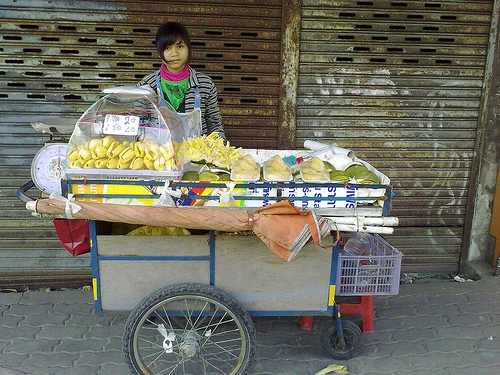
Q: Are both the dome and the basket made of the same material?
A: Yes, both the dome and the basket are made of plastic.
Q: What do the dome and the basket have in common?
A: The material, both the dome and the basket are plastic.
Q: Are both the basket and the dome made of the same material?
A: Yes, both the basket and the dome are made of plastic.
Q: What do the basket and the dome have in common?
A: The material, both the basket and the dome are plastic.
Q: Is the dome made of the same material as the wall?
A: No, the dome is made of plastic and the wall is made of metal.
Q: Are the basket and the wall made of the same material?
A: No, the basket is made of plastic and the wall is made of metal.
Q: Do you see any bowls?
A: No, there are no bowls.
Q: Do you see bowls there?
A: No, there are no bowls.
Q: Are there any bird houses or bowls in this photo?
A: No, there are no bowls or bird houses.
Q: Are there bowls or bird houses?
A: No, there are no bowls or bird houses.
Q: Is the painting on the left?
A: No, the painting is on the right of the image.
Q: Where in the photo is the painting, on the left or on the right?
A: The painting is on the right of the image.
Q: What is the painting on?
A: The painting is on the wall.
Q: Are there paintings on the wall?
A: Yes, there is a painting on the wall.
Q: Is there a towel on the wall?
A: No, there is a painting on the wall.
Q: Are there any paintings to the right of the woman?
A: Yes, there is a painting to the right of the woman.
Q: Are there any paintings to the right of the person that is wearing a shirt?
A: Yes, there is a painting to the right of the woman.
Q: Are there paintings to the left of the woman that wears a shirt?
A: No, the painting is to the right of the woman.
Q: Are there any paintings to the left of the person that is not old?
A: No, the painting is to the right of the woman.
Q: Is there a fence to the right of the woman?
A: No, there is a painting to the right of the woman.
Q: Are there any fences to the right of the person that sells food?
A: No, there is a painting to the right of the woman.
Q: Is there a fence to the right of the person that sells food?
A: No, there is a painting to the right of the woman.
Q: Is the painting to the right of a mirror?
A: No, the painting is to the right of the woman.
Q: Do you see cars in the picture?
A: No, there are no cars.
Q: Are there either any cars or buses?
A: No, there are no cars or buses.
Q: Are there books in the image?
A: No, there are no books.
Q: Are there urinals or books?
A: No, there are no books or urinals.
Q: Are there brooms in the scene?
A: No, there are no brooms.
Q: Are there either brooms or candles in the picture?
A: No, there are no brooms or candles.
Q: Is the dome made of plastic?
A: Yes, the dome is made of plastic.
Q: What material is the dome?
A: The dome is made of plastic.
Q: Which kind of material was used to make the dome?
A: The dome is made of plastic.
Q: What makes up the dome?
A: The dome is made of plastic.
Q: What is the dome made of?
A: The dome is made of plastic.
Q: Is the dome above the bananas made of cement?
A: No, the dome is made of plastic.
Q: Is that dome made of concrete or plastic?
A: The dome is made of plastic.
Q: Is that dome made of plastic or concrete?
A: The dome is made of plastic.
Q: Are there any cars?
A: No, there are no cars.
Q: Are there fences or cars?
A: No, there are no cars or fences.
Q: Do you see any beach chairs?
A: No, there are no beach chairs.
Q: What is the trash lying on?
A: The trash is lying on the sidewalk.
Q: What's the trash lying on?
A: The trash is lying on the sidewalk.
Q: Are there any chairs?
A: No, there are no chairs.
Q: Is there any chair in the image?
A: No, there are no chairs.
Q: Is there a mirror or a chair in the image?
A: No, there are no chairs or mirrors.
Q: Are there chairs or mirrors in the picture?
A: No, there are no chairs or mirrors.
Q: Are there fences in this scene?
A: No, there are no fences.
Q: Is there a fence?
A: No, there are no fences.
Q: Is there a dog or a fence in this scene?
A: No, there are no fences or dogs.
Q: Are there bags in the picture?
A: Yes, there is a bag.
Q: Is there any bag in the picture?
A: Yes, there is a bag.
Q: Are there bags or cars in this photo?
A: Yes, there is a bag.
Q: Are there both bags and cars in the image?
A: No, there is a bag but no cars.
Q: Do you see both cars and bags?
A: No, there is a bag but no cars.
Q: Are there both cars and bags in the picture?
A: No, there is a bag but no cars.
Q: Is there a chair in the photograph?
A: No, there are no chairs.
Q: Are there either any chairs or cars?
A: No, there are no chairs or cars.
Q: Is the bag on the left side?
A: Yes, the bag is on the left of the image.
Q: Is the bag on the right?
A: No, the bag is on the left of the image.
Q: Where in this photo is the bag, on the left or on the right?
A: The bag is on the left of the image.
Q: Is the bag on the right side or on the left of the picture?
A: The bag is on the left of the image.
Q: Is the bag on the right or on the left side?
A: The bag is on the left of the image.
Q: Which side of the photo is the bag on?
A: The bag is on the left of the image.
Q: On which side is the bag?
A: The bag is on the left of the image.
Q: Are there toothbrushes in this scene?
A: No, there are no toothbrushes.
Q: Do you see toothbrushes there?
A: No, there are no toothbrushes.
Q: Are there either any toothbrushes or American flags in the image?
A: No, there are no toothbrushes or American flags.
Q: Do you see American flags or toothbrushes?
A: No, there are no toothbrushes or American flags.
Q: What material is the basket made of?
A: The basket is made of plastic.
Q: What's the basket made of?
A: The basket is made of plastic.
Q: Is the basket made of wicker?
A: No, the basket is made of plastic.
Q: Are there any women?
A: Yes, there is a woman.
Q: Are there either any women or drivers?
A: Yes, there is a woman.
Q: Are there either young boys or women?
A: Yes, there is a young woman.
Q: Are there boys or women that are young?
A: Yes, the woman is young.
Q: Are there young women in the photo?
A: Yes, there is a young woman.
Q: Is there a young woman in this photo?
A: Yes, there is a young woman.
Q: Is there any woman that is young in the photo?
A: Yes, there is a young woman.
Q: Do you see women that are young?
A: Yes, there is a woman that is young.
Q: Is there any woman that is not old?
A: Yes, there is an young woman.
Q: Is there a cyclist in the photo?
A: No, there are no cyclists.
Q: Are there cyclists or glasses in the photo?
A: No, there are no cyclists or glasses.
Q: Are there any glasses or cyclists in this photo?
A: No, there are no cyclists or glasses.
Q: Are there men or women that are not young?
A: No, there is a woman but she is young.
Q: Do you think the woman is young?
A: Yes, the woman is young.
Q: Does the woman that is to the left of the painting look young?
A: Yes, the woman is young.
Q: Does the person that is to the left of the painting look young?
A: Yes, the woman is young.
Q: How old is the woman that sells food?
A: The woman is young.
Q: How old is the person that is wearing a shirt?
A: The woman is young.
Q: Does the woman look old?
A: No, the woman is young.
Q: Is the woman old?
A: No, the woman is young.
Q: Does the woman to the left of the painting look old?
A: No, the woman is young.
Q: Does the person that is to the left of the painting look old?
A: No, the woman is young.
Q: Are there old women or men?
A: No, there is a woman but she is young.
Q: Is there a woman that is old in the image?
A: No, there is a woman but she is young.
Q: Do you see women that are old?
A: No, there is a woman but she is young.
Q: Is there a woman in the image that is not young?
A: No, there is a woman but she is young.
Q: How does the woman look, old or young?
A: The woman is young.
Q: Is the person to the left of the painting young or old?
A: The woman is young.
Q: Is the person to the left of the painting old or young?
A: The woman is young.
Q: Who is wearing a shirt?
A: The woman is wearing a shirt.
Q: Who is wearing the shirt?
A: The woman is wearing a shirt.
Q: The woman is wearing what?
A: The woman is wearing a shirt.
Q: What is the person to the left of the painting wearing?
A: The woman is wearing a shirt.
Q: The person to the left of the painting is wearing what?
A: The woman is wearing a shirt.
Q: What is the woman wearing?
A: The woman is wearing a shirt.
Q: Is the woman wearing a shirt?
A: Yes, the woman is wearing a shirt.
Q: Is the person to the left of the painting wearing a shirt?
A: Yes, the woman is wearing a shirt.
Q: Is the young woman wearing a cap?
A: No, the woman is wearing a shirt.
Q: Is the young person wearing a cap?
A: No, the woman is wearing a shirt.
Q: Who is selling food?
A: The woman is selling food.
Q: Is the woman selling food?
A: Yes, the woman is selling food.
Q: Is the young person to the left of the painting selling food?
A: Yes, the woman is selling food.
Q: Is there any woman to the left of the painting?
A: Yes, there is a woman to the left of the painting.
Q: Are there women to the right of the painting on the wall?
A: No, the woman is to the left of the painting.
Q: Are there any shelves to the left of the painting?
A: No, there is a woman to the left of the painting.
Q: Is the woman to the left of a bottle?
A: No, the woman is to the left of the painting.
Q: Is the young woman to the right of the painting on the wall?
A: No, the woman is to the left of the painting.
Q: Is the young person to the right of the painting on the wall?
A: No, the woman is to the left of the painting.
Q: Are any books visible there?
A: No, there are no books.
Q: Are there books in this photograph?
A: No, there are no books.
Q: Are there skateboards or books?
A: No, there are no books or skateboards.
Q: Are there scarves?
A: Yes, there is a scarf.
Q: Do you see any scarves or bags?
A: Yes, there is a scarf.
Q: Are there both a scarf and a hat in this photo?
A: No, there is a scarf but no hats.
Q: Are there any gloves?
A: No, there are no gloves.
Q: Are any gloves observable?
A: No, there are no gloves.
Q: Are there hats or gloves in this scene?
A: No, there are no gloves or hats.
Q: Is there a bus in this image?
A: No, there are no buses.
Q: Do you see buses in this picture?
A: No, there are no buses.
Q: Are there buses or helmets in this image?
A: No, there are no buses or helmets.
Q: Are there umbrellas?
A: Yes, there is an umbrella.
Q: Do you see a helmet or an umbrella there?
A: Yes, there is an umbrella.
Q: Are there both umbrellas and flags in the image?
A: No, there is an umbrella but no flags.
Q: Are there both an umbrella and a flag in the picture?
A: No, there is an umbrella but no flags.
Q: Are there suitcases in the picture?
A: No, there are no suitcases.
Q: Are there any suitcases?
A: No, there are no suitcases.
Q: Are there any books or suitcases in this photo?
A: No, there are no suitcases or books.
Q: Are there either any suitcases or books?
A: No, there are no suitcases or books.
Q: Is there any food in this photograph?
A: Yes, there is food.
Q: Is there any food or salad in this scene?
A: Yes, there is food.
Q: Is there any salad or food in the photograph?
A: Yes, there is food.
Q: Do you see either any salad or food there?
A: Yes, there is food.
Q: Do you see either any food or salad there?
A: Yes, there is food.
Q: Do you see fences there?
A: No, there are no fences.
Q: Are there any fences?
A: No, there are no fences.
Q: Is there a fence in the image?
A: No, there are no fences.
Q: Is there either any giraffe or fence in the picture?
A: No, there are no fences or giraffes.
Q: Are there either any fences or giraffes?
A: No, there are no fences or giraffes.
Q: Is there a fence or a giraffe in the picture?
A: No, there are no fences or giraffes.